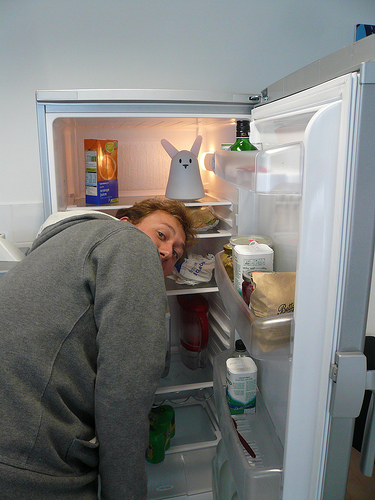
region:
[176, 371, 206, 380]
shelf in the refrigerator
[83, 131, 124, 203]
orange juice in regrigerator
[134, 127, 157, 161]
back wall in refrigerator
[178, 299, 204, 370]
pitcher in the refrigerator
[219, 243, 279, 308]
items on refrigerator shelf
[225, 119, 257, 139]
black top on bottle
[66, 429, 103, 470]
pocket on gray jacket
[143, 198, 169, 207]
part of man's hair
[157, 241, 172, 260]
nose on the man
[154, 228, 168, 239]
eye on the man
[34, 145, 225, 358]
a man in a refrigerator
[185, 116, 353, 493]
a white refrigerator door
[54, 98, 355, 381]
a refrigerator with the door open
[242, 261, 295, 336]
a paper bag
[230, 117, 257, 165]
a green bottle with a black lid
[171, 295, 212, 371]
a red canister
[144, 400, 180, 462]
a pack of can drinks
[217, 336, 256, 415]
a clear bottle with a black lid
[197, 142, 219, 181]
a light on in a refrigerator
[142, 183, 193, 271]
a man with blonde hair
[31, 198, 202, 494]
Man leaning into a refrigerator.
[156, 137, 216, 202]
White rabbit shaped item on the shelf.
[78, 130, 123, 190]
Box of orange juice on the shelf.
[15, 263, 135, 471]
The jacket is grey.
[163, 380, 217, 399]
Edge of the shelf is white.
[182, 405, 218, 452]
The shelf is clear.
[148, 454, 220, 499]
Drawer in the bottom.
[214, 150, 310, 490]
Shelves on the door.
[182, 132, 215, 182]
Light in the refrigerator.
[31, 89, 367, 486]
Inside the refrigerator is white.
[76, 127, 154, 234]
carton of orange juice in fridge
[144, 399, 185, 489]
6 pack of soda in fridge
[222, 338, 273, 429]
carton of milk in the fridge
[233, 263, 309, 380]
pack of cookies in fridge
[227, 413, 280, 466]
plastic spoon in fridge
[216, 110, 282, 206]
greem bottle in fridge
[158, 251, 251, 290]
plastic bag in fridge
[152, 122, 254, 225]
toy cat in fridge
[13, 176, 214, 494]
boy standing with head in fridge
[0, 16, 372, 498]
fridge door opened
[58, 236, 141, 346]
person wearing a grey sweater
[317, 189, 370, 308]
the refrigerator is white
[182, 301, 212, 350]
a red container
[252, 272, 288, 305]
a brown bag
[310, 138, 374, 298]
door of the refrigerator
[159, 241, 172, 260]
the persons nose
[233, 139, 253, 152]
a green bottle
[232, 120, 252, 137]
a black top on the green bottle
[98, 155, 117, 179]
picture of an orange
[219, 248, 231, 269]
a jar